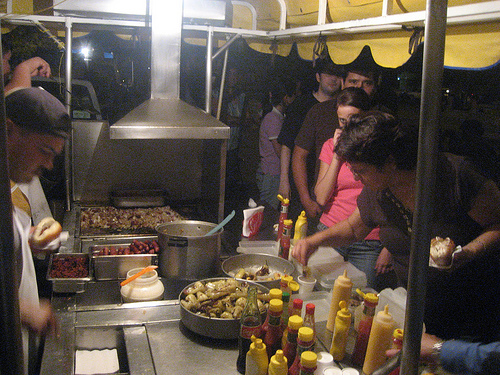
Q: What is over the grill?
A: Fan hood.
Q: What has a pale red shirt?
A: The young girl.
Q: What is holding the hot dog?
A: The guy.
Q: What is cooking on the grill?
A: The good.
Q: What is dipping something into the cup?
A: The guy.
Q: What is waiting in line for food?
A: The people.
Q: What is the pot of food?
A: Cooking.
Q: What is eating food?
A: The woman.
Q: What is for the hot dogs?
A: The array of condiments.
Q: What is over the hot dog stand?
A: The yellow awning.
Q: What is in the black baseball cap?
A: The man.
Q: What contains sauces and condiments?
A: Plastic bottles.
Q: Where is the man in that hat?
A: Behind the counter.